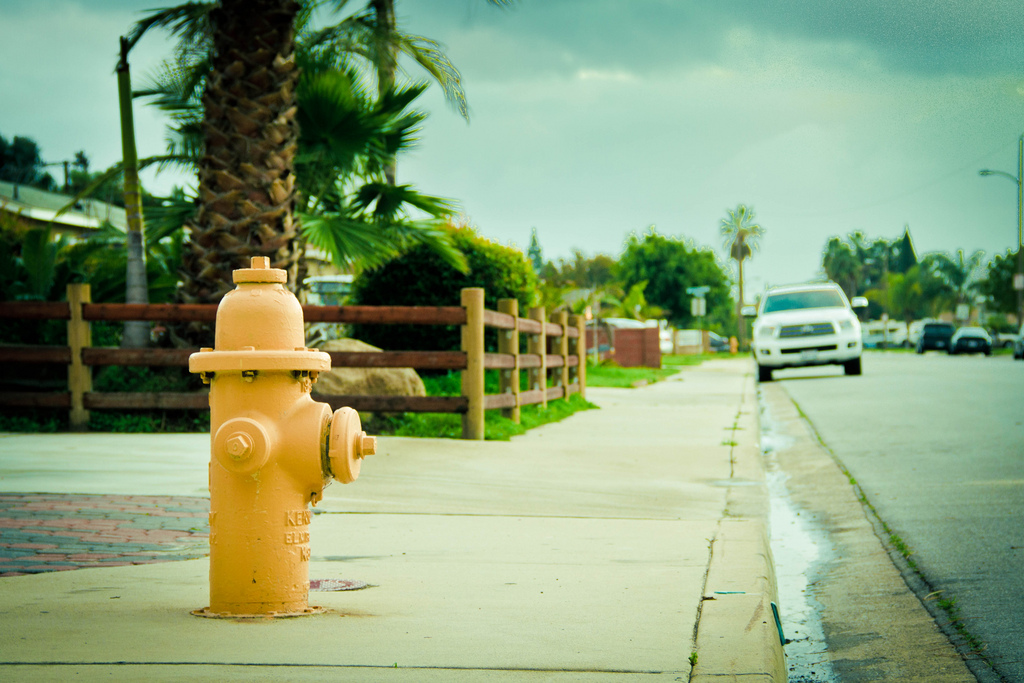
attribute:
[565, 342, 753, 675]
sidewalk — stretching to the horizon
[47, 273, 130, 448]
fence post — short, round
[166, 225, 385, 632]
fire hydrant — yellow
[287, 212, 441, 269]
leaves — large, green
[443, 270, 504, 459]
fence post — short, round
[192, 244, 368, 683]
hydrant — small and  yellow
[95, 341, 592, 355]
fence — large and wooden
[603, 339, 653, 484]
grass — green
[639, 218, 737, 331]
tree — green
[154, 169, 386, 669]
hydrant — yellow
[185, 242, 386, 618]
fire hydrant — yellow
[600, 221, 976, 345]
tree — Palm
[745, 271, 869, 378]
truck — White 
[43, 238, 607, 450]
fence — Wood 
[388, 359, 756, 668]
sidewalk — patch 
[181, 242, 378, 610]
hydrant — fire  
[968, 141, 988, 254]
pole — curved light 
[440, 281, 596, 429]
fence — wooden 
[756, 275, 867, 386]
truck — white